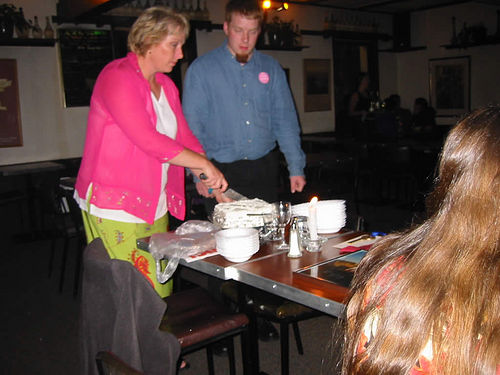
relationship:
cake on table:
[207, 179, 283, 236] [226, 254, 309, 307]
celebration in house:
[28, 46, 386, 336] [4, 4, 493, 371]